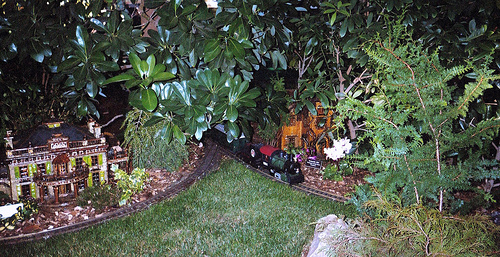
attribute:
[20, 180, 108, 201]
columns — brown 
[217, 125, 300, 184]
train — under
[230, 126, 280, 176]
train — green , black 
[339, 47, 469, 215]
little tree — covering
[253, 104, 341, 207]
train — toy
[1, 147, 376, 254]
grass — green 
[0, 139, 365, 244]
train tracks — around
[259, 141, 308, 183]
train — black , green 